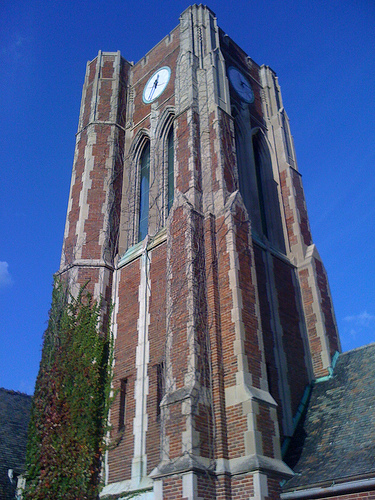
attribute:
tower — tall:
[15, 5, 338, 491]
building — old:
[26, 2, 341, 498]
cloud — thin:
[1, 258, 16, 288]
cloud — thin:
[335, 304, 373, 349]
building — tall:
[7, 0, 364, 375]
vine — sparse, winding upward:
[152, 193, 206, 486]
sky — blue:
[305, 100, 351, 169]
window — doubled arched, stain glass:
[135, 136, 150, 244]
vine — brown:
[164, 219, 198, 320]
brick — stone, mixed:
[76, 54, 115, 307]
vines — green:
[28, 267, 108, 495]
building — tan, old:
[90, 42, 339, 314]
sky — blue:
[1, 4, 111, 314]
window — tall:
[127, 129, 155, 232]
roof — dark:
[300, 338, 373, 478]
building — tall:
[35, 3, 374, 498]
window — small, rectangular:
[155, 361, 167, 423]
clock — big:
[138, 63, 174, 109]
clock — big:
[225, 64, 263, 107]